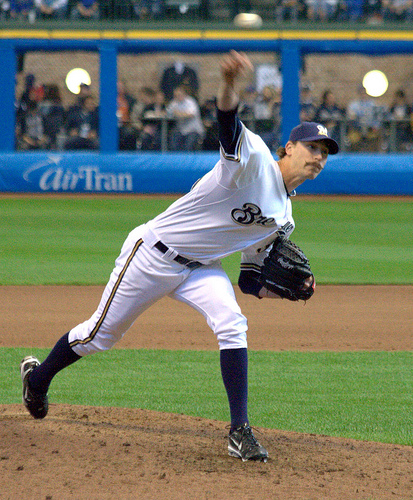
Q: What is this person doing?
A: Throwing.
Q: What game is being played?
A: Baseball.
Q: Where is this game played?
A: Baseball field.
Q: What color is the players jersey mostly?
A: White.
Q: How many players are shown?
A: One.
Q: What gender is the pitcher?
A: Male.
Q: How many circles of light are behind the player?
A: Two.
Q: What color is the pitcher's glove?
A: Black.